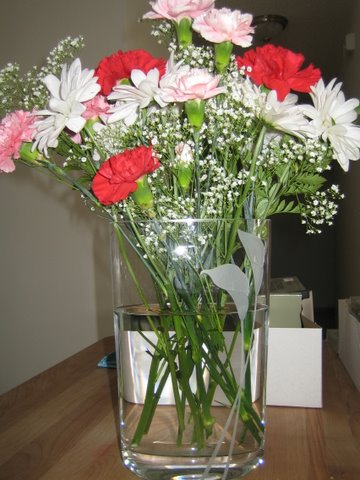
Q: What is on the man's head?
A: A cap.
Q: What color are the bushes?
A: Green.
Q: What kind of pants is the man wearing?
A: Jeans.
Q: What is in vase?
A: Flowers.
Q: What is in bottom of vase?
A: Water.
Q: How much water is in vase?
A: Half full.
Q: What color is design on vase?
A: White.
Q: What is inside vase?
A: Water.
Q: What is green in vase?
A: Stems.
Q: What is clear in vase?
A: Water.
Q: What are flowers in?
A: Vase with etching.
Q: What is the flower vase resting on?
A: Brown surface.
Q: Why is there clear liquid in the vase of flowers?
A: To help the flowers stay fresh longer.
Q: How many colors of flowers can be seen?
A: 3.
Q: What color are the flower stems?
A: Green.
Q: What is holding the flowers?
A: A clear tall vase.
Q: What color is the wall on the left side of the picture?
A: White.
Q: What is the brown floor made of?
A: Wood.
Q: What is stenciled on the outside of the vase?
A: Leaves and stems.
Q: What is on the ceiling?
A: Light fixture.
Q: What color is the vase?
A: Clear.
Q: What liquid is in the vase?
A: Water.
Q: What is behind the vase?
A: Box.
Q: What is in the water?
A: Stems.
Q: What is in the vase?
A: Flowers.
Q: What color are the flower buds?
A: White.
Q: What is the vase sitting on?
A: Table.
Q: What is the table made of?
A: Wood.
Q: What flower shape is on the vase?
A: Lily.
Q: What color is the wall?
A: White.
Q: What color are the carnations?
A: Pink.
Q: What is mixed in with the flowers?
A: Baby's breath.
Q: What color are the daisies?
A: White.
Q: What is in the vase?
A: Assorted flowers.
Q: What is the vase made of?
A: Glass.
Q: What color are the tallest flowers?
A: Pink.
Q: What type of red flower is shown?
A: Carnation.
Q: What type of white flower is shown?
A: Daisy.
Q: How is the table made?
A: Of wood.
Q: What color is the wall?
A: White.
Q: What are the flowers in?
A: A vase.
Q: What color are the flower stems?
A: Green.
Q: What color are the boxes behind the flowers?
A: White.